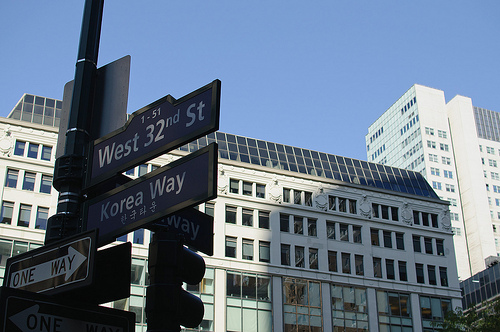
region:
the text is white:
[97, 100, 206, 165]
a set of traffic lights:
[144, 225, 204, 330]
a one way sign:
[7, 235, 86, 289]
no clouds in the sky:
[0, 0, 495, 160]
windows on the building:
[227, 270, 269, 303]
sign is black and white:
[4, 238, 91, 293]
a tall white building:
[364, 81, 499, 277]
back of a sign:
[55, 55, 130, 158]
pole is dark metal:
[47, 0, 102, 244]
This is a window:
[238, 199, 257, 226]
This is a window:
[228, 175, 245, 196]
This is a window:
[255, 181, 266, 199]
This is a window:
[220, 199, 237, 225]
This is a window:
[257, 205, 274, 232]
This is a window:
[278, 207, 291, 237]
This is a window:
[292, 211, 307, 236]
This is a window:
[278, 238, 294, 267]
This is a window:
[280, 270, 297, 305]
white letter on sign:
[96, 140, 116, 170]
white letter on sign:
[112, 143, 124, 158]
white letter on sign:
[121, 138, 133, 155]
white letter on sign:
[129, 129, 142, 152]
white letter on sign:
[98, 200, 113, 222]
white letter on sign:
[108, 200, 120, 215]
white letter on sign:
[117, 197, 128, 217]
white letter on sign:
[146, 175, 166, 198]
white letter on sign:
[163, 175, 175, 194]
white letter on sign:
[173, 172, 188, 193]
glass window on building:
[432, 210, 439, 228]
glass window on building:
[421, 210, 430, 225]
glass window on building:
[412, 209, 420, 224]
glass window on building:
[390, 207, 398, 223]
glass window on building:
[381, 203, 389, 219]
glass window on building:
[371, 201, 377, 217]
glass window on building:
[439, 264, 447, 285]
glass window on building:
[428, 262, 438, 283]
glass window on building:
[416, 261, 426, 283]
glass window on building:
[295, 243, 306, 265]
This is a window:
[243, 176, 253, 198]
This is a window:
[254, 176, 268, 198]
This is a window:
[292, 240, 309, 268]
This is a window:
[306, 242, 321, 273]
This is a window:
[329, 245, 339, 276]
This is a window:
[371, 252, 384, 276]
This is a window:
[366, 219, 381, 241]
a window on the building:
[243, 236, 247, 250]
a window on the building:
[258, 237, 275, 259]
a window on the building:
[227, 231, 236, 258]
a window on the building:
[312, 246, 315, 268]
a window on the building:
[327, 243, 332, 260]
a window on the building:
[352, 249, 360, 264]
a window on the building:
[272, 225, 282, 240]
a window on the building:
[290, 214, 298, 232]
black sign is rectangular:
[82, 143, 215, 239]